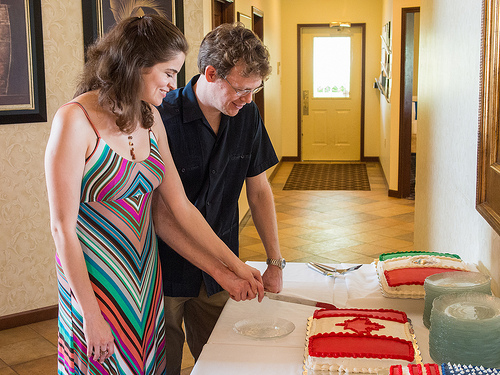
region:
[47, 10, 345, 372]
a woman and a man cutting a cake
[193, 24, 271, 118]
the head of a man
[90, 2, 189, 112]
the head of a woman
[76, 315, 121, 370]
the hand of a woman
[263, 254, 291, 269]
a watch on a wrist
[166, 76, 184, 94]
the nose of a woman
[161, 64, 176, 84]
the eye of a woman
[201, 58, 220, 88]
the ear of a man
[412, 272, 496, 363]
two stacks of plates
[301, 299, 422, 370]
a white and red cake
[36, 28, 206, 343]
woman wearing a colorful dress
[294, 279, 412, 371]
red and white canadian cake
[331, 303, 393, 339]
the canadian leaf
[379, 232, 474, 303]
a green white and red cake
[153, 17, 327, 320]
a man wearing a navy blue shirt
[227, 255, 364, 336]
knife about to cut a cake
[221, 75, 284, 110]
a man wearing glasses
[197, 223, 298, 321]
three hands holding a knife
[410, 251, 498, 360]
plastic plates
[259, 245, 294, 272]
watch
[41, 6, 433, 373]
A couple cutting a cake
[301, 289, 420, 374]
A red and white oblong cake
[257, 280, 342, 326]
A silver cake knife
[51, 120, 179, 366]
A striped spaghetti strap dress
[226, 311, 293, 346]
A clear glass plate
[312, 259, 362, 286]
A silver serving piece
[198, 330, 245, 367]
A white tablecloth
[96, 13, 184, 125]
Long brown hair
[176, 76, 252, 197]
A black or dark blue shirt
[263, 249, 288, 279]
A silver wrist watch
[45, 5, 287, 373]
a man and a woman about to cut a cake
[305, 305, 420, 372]
a cake with a Canada flag frosting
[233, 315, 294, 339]
a plate on a table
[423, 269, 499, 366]
a stack of glass plates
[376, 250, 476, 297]
a cake with a Mexico flag frosting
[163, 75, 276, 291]
man wearing a blue shirt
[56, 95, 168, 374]
woman wearing a colorful dress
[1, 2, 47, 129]
a framed picture on the wall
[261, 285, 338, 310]
edge of a knife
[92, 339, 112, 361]
Woman wearing a ring on finger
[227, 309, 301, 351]
Clear plate on white table cloth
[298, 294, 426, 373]
Red and white cake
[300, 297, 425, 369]
Canadian flag on a cake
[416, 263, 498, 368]
Two stacks of clear plates on table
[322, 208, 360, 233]
Tile on a hallway floor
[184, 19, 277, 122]
Man wearing wire rim glasses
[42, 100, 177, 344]
Woman wearing colorful dress